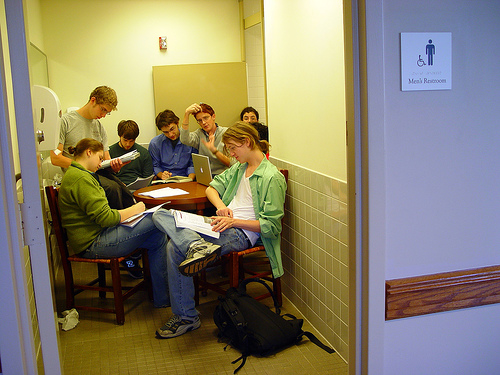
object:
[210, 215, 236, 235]
hand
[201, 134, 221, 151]
hand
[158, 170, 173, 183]
hand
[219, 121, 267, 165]
head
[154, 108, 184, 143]
head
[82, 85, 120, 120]
head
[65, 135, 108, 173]
head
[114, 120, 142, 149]
head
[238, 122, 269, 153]
man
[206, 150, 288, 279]
shirt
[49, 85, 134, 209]
man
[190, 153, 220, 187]
laptop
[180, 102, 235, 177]
man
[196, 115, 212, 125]
glasses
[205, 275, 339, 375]
backpack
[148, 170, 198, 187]
paper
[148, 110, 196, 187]
man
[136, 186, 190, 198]
book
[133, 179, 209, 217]
table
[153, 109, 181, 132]
hair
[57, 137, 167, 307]
woman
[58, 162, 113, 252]
sweater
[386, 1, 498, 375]
wall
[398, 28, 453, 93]
sign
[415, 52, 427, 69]
handicap symbol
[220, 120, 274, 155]
hair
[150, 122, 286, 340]
man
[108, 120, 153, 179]
man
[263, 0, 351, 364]
wall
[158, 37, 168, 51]
fire alarm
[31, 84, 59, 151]
dispenser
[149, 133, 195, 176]
shirt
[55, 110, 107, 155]
t-shirt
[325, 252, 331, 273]
tiles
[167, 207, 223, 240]
book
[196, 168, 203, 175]
apple sign